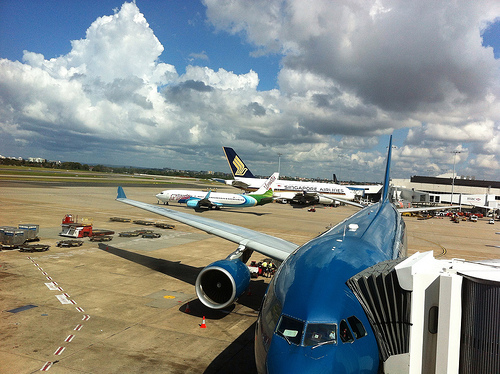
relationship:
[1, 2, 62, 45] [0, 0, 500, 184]
part of sky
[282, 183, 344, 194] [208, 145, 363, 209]
lettering on plane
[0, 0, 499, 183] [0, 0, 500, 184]
cloud hanging in sky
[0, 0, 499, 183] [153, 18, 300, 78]
cloud hanging in blue sky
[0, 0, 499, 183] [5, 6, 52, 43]
cloud hanging in sky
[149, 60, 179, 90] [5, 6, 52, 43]
cloud hanging in sky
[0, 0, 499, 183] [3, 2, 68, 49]
cloud hanging in blue sky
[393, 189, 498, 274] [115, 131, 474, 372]
walkway connected to plane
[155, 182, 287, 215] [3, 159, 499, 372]
planes at airport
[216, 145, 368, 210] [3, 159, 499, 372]
plane at airport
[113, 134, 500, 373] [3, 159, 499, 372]
plane at airport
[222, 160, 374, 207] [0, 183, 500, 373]
plane on tarmac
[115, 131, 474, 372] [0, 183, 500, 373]
plane on tarmac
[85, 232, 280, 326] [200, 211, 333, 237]
shadow on ground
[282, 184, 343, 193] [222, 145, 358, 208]
writing on plane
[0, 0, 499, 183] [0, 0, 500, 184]
cloud in sky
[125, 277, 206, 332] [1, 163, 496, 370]
spot on ground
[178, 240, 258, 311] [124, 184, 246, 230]
jet engine under wing